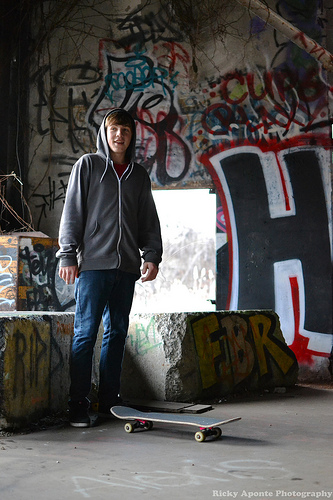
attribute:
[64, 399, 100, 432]
shoe — black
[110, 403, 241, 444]
skateboard — black, long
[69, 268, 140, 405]
jeans — blue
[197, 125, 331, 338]
letter — white, large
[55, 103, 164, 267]
hoodie — gray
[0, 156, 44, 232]
wire — barbed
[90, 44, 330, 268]
walls — cement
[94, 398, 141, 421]
sneaker — white soled 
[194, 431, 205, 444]
wheel — white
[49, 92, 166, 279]
hoodie — gray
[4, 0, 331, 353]
graffiti — colored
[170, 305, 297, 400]
wall — concrete